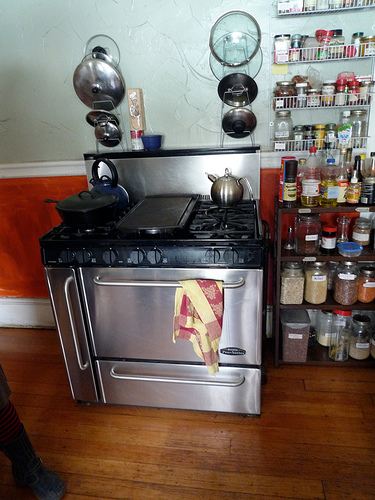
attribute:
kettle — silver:
[196, 162, 246, 217]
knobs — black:
[69, 245, 249, 268]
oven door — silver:
[77, 263, 268, 379]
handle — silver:
[55, 277, 91, 371]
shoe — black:
[7, 433, 79, 499]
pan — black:
[43, 190, 120, 237]